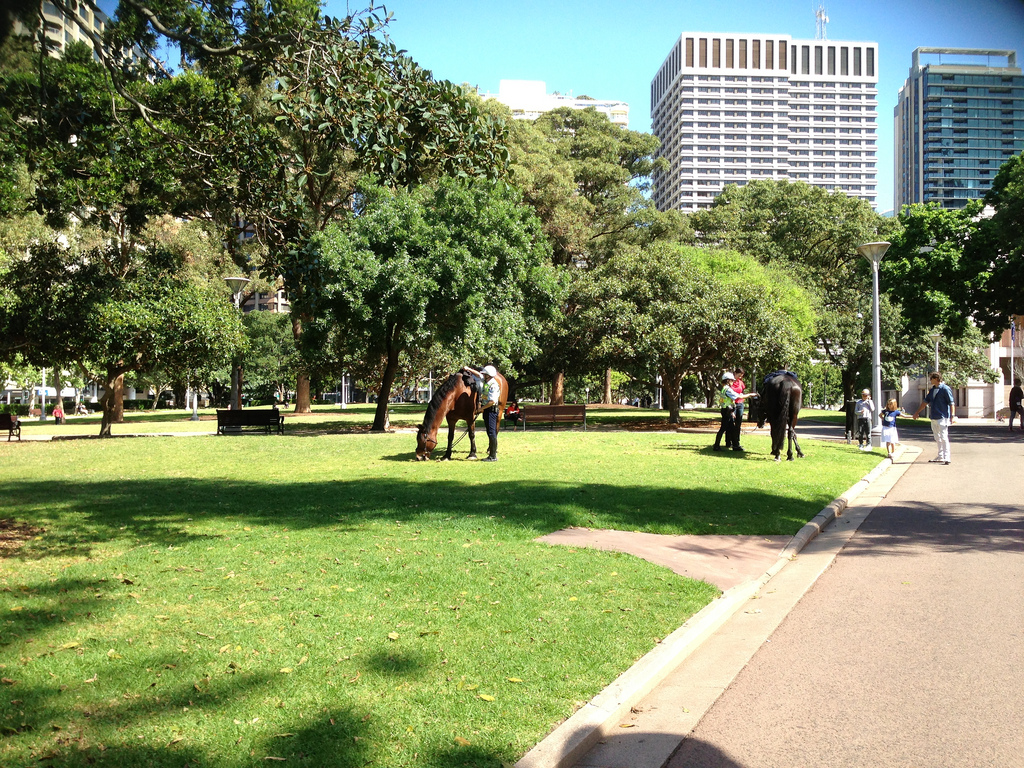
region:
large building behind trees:
[646, 2, 884, 361]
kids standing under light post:
[854, 224, 902, 455]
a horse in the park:
[408, 359, 523, 457]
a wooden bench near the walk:
[209, 386, 293, 441]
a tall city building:
[634, 29, 892, 397]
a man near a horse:
[468, 355, 519, 476]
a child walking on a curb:
[879, 384, 900, 461]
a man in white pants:
[918, 358, 960, 463]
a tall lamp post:
[844, 225, 896, 442]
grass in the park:
[126, 483, 525, 698]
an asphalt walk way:
[588, 438, 1009, 752]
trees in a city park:
[110, 55, 522, 420]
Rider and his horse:
[384, 350, 522, 474]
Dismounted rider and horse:
[710, 347, 808, 472]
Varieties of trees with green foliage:
[28, 7, 635, 340]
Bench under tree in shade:
[187, 383, 304, 440]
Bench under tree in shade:
[517, 374, 607, 436]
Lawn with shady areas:
[44, 450, 405, 752]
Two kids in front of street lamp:
[847, 225, 909, 467]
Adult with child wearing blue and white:
[871, 347, 971, 481]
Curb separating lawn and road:
[463, 580, 761, 757]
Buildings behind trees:
[24, 9, 1008, 373]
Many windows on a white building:
[673, 78, 875, 193]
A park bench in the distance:
[519, 388, 589, 452]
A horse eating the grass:
[403, 359, 514, 472]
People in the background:
[842, 357, 972, 470]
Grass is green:
[296, 543, 543, 642]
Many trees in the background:
[171, 65, 775, 388]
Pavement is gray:
[846, 570, 955, 727]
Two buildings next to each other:
[645, 6, 1011, 208]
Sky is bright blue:
[476, 0, 622, 38]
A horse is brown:
[390, 363, 530, 485]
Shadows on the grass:
[181, 461, 504, 544]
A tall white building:
[624, 8, 910, 281]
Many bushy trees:
[304, 59, 850, 390]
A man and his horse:
[392, 328, 540, 470]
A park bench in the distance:
[204, 393, 296, 436]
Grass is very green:
[235, 552, 388, 597]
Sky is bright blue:
[475, 7, 592, 64]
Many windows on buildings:
[664, 30, 1007, 185]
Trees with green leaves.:
[80, 33, 463, 353]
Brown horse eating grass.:
[411, 356, 526, 464]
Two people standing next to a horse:
[712, 356, 811, 462]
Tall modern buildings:
[642, 27, 1022, 252]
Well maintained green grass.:
[10, 465, 554, 748]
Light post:
[858, 234, 888, 449]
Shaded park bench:
[203, 399, 290, 432]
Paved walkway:
[750, 472, 998, 751]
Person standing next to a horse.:
[472, 355, 508, 466]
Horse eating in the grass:
[397, 358, 537, 473]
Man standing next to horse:
[385, 356, 542, 464]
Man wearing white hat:
[455, 342, 514, 475]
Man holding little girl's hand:
[840, 339, 968, 498]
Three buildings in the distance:
[410, 10, 1020, 244]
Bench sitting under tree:
[138, 386, 313, 448]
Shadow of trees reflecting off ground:
[31, 473, 990, 759]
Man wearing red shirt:
[721, 358, 753, 415]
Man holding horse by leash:
[360, 342, 547, 491]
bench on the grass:
[206, 400, 312, 433]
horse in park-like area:
[411, 353, 536, 489]